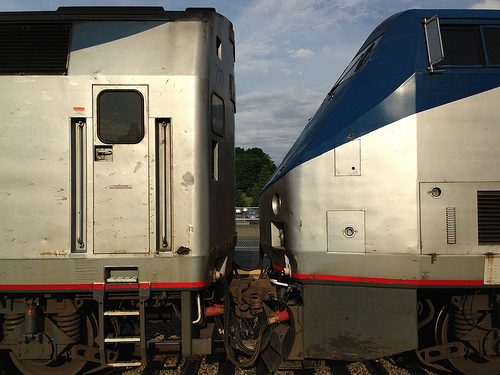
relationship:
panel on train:
[324, 209, 367, 253] [2, 5, 497, 375]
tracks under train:
[1, 350, 499, 374] [2, 5, 497, 375]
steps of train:
[93, 283, 151, 371] [2, 5, 497, 375]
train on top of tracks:
[2, 5, 497, 375] [1, 350, 499, 374]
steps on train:
[93, 283, 151, 371] [2, 5, 497, 375]